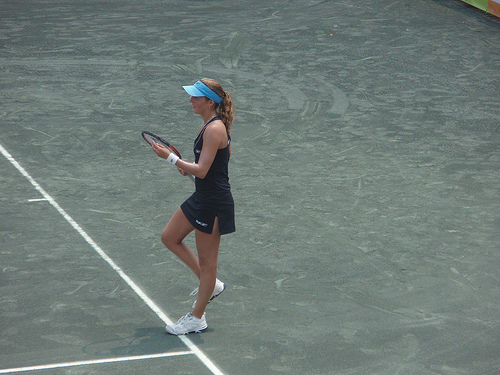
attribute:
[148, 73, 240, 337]
woman — playing, standing, dressed, athletic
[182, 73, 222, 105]
visor — blue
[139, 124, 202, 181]
racket — black, red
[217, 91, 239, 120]
ponytail — blonde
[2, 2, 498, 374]
court — grey, green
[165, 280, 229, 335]
shoes — white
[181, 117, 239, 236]
dress — black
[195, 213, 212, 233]
logo — white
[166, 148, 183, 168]
wristband — thick, white